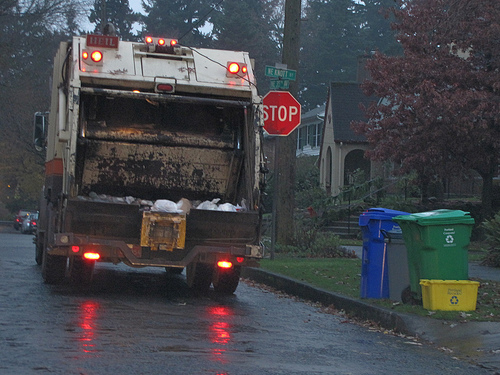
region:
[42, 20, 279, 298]
the garbage truck on the street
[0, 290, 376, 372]
the street is wet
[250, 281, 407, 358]
dead leaves in the gutter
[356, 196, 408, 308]
the blue recycling bin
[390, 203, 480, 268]
the green recycling bin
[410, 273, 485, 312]
the yellow recycling bin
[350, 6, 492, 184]
the tree with purple leaves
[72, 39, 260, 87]
the red lights on the truck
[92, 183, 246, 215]
garbage inside the garbage truck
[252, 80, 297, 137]
the stop sign beside the truck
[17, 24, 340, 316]
a trash truck stopped at a sign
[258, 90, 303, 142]
a red and white stop sign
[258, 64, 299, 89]
two green and white street signs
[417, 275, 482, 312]
a yellow recycling bin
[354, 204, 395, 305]
a blue trash can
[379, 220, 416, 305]
a gray trash can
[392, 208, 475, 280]
a green trash can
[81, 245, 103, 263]
the brake light of a trash truck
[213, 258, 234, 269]
the brake light of a trash truck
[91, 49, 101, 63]
the brake light of a trash truck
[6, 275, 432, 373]
the ground is wet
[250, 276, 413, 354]
brown leaves in the gutter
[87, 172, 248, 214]
garbage in the garbage truck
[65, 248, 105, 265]
red light on the garbage truck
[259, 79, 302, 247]
the stop sign beside the truck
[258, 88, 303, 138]
red and white stop sign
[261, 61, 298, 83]
green and white street sign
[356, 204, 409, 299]
blue trash can on the grass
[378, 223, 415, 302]
gray trash can with black handle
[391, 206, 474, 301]
green trash can on the grass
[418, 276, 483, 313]
yellow recycling bin on the grass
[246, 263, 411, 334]
gray curb near the street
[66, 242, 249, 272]
brake lights on the trash truck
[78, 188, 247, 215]
trash in the back of the truck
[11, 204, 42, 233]
cars in front of the trash truck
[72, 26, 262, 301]
The back of a garbage truck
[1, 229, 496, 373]
The road is very wet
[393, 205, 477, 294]
A red and white stop sign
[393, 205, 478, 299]
A large green garbage bin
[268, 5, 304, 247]
A tall brown telephone pole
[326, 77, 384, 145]
Black roof of a house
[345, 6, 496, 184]
Red leaves on trees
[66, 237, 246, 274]
Four red rear lights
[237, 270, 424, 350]
Leaves on the side of a road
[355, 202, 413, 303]
A blue garbage bin